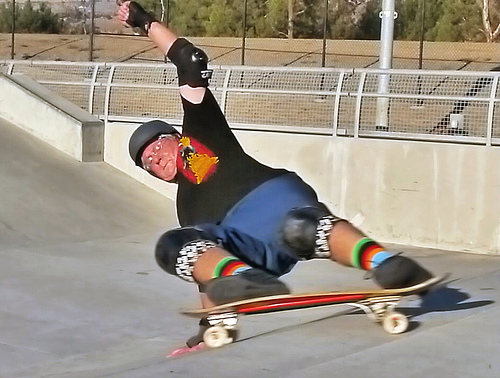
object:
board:
[179, 270, 456, 350]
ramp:
[0, 116, 183, 251]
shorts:
[176, 173, 332, 282]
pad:
[167, 38, 213, 89]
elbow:
[187, 50, 211, 64]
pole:
[376, 0, 397, 132]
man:
[117, 0, 433, 359]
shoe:
[205, 267, 290, 306]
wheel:
[383, 312, 410, 335]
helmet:
[128, 119, 182, 165]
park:
[1, 58, 499, 377]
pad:
[278, 203, 349, 260]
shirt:
[176, 85, 296, 229]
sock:
[350, 236, 393, 272]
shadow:
[428, 69, 499, 133]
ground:
[342, 327, 500, 376]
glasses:
[141, 135, 177, 172]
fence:
[230, 64, 499, 145]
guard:
[125, 0, 159, 38]